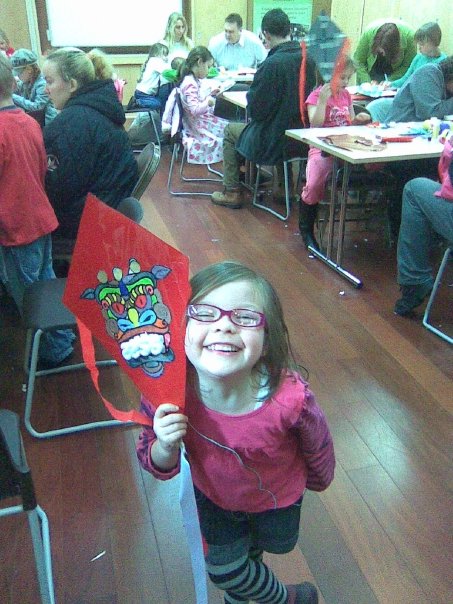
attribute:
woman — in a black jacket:
[34, 41, 144, 212]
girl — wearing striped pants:
[207, 540, 288, 602]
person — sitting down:
[27, 37, 152, 256]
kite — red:
[69, 188, 186, 406]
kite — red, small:
[72, 200, 202, 410]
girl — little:
[174, 54, 242, 162]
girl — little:
[322, 157, 404, 253]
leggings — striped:
[190, 554, 308, 602]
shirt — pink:
[127, 362, 343, 524]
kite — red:
[35, 187, 212, 432]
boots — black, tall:
[279, 194, 332, 250]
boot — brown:
[201, 177, 263, 214]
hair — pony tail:
[28, 26, 121, 95]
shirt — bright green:
[344, 3, 430, 87]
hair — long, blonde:
[154, 0, 203, 117]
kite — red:
[52, 154, 219, 475]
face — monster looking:
[55, 251, 199, 399]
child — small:
[97, 227, 345, 602]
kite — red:
[38, 175, 204, 436]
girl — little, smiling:
[61, 191, 355, 600]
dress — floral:
[171, 73, 242, 164]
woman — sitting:
[32, 37, 158, 237]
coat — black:
[36, 77, 146, 256]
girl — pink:
[296, 45, 371, 252]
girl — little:
[121, 36, 181, 104]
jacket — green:
[351, 9, 433, 97]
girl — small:
[133, 243, 332, 600]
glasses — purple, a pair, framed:
[164, 270, 311, 355]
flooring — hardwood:
[6, 178, 452, 599]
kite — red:
[57, 189, 194, 418]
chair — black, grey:
[16, 193, 151, 440]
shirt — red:
[2, 104, 60, 251]